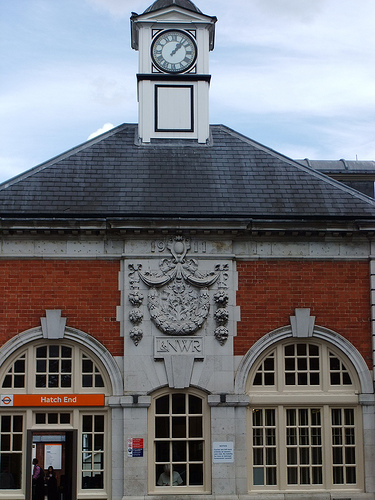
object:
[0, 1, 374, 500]
building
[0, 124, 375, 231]
roof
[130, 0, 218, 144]
tower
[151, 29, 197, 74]
clock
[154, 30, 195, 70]
face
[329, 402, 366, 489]
windows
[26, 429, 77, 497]
entryway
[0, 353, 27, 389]
windows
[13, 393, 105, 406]
sign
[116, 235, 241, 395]
sculpture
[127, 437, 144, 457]
sign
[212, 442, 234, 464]
sign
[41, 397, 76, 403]
"hatch end"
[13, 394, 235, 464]
signs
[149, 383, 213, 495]
window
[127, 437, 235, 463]
signs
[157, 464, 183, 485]
person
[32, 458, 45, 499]
person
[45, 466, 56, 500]
person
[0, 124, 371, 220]
shingles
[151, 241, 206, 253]
1911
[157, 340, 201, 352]
sign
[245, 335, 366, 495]
window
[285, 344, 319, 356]
panes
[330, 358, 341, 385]
panes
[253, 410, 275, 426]
panes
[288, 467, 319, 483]
panes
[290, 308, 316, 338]
stone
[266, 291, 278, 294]
brick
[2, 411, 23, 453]
window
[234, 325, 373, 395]
arch